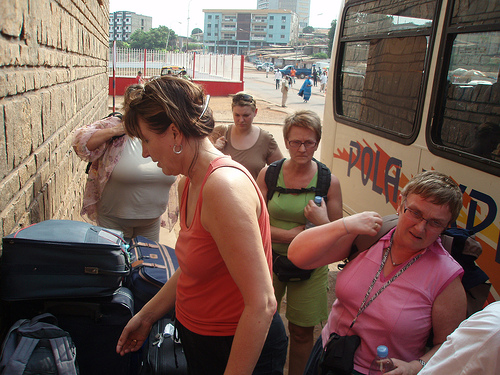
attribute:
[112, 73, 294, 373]
passenger — ready, older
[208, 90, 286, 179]
passenger — ready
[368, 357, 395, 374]
water — bottled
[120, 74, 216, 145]
hair — clipped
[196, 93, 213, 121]
clip — silver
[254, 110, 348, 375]
passenger — woman, old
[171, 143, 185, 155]
earring — hoop, silver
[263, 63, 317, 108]
people — walking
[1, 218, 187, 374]
luggauges — piled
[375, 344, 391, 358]
lid — blue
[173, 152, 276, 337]
tank top — orange, sleeveless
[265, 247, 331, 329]
shorts — green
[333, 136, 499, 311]
logo — multi color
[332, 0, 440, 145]
window — clear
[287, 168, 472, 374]
passenger — older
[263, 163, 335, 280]
tank top — green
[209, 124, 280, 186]
shirt — brown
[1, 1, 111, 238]
wall — brown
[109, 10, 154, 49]
building — white, tan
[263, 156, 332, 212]
straps — black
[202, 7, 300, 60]
building — light blue, four story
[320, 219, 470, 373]
shirt — pink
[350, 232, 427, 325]
lanyard — black, white